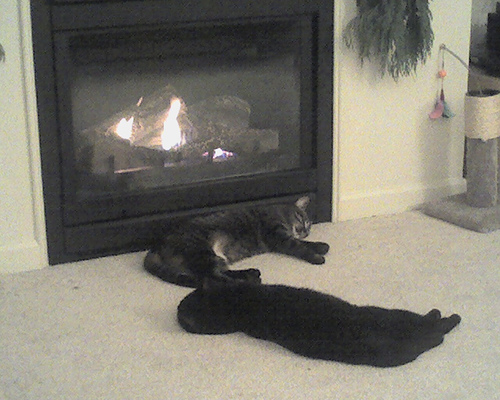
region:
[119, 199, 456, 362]
two cats lying on the floor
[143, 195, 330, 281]
a cat getting warm by a fireplace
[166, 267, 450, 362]
a large black cat on the floor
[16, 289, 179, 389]
carpet on the floor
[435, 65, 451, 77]
a yellow ball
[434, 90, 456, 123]
a pink and blue ornament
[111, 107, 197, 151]
hot fire in a fireplace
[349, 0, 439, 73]
a green fern hanging down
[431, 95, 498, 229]
a beige cat scratch stand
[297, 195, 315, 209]
a pointy cat ear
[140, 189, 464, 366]
There are two cats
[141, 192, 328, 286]
The cat is striped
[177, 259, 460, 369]
The cat is black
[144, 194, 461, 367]
The cats are lying down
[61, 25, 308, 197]
Fire in the fire place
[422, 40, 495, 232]
Brown cat scratching post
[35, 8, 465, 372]
The cats are in front of the fire place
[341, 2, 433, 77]
Leaves hanging from the wall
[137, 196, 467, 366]
The cats are on the carpet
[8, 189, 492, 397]
The carpet is beige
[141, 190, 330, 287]
a grey cat by a fireplace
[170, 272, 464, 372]
a black cat on the carpet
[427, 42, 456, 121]
a cat toy hanging down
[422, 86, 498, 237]
a grey scratching post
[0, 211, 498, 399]
an off-white carpet under two cats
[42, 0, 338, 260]
a black fireplace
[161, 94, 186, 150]
fire in a fireplace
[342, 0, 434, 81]
a green plant hanging down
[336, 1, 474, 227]
a white wall next to a fireplace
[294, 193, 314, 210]
an ear of a cat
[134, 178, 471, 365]
two cats lying on a carpet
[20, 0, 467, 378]
two cats in front a fireplace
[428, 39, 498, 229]
a stand for cats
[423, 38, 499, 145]
a toy for a cat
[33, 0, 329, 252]
the fireplace has fire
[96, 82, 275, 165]
fire made with logs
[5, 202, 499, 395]
the carpet is color beige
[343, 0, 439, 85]
a plant hangs from a wall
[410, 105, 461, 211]
a show on a wall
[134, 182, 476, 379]
cats are lying on the side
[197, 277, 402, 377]
black cat laying on floor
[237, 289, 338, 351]
black fur on cat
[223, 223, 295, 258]
gray fur on cat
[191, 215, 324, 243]
gray cat laying on floor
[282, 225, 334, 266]
right leg on cat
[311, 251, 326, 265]
right paw on cat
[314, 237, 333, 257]
left paw on cat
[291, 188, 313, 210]
right ear on cat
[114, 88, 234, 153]
bright fire in fireplace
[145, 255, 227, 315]
long tail on cat